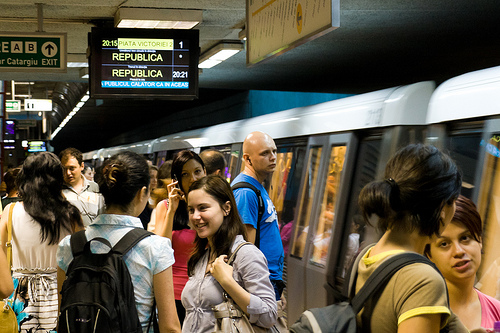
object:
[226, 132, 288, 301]
man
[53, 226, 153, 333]
backpack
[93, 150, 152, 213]
hair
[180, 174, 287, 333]
woman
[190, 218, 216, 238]
smile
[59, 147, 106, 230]
man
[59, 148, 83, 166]
hair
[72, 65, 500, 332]
train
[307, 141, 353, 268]
window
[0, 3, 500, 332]
station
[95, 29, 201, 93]
sign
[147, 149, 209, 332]
woman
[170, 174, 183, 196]
phone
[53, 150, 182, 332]
woman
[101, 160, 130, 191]
ponytail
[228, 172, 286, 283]
shirt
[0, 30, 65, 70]
sign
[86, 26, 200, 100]
monitor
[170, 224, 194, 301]
shirt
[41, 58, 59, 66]
exit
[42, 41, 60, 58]
circle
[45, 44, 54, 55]
arrow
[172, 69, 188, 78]
times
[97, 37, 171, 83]
route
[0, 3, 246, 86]
ceiling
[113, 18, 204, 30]
light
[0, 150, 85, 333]
people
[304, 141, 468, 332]
women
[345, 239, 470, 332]
shirt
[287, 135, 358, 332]
door